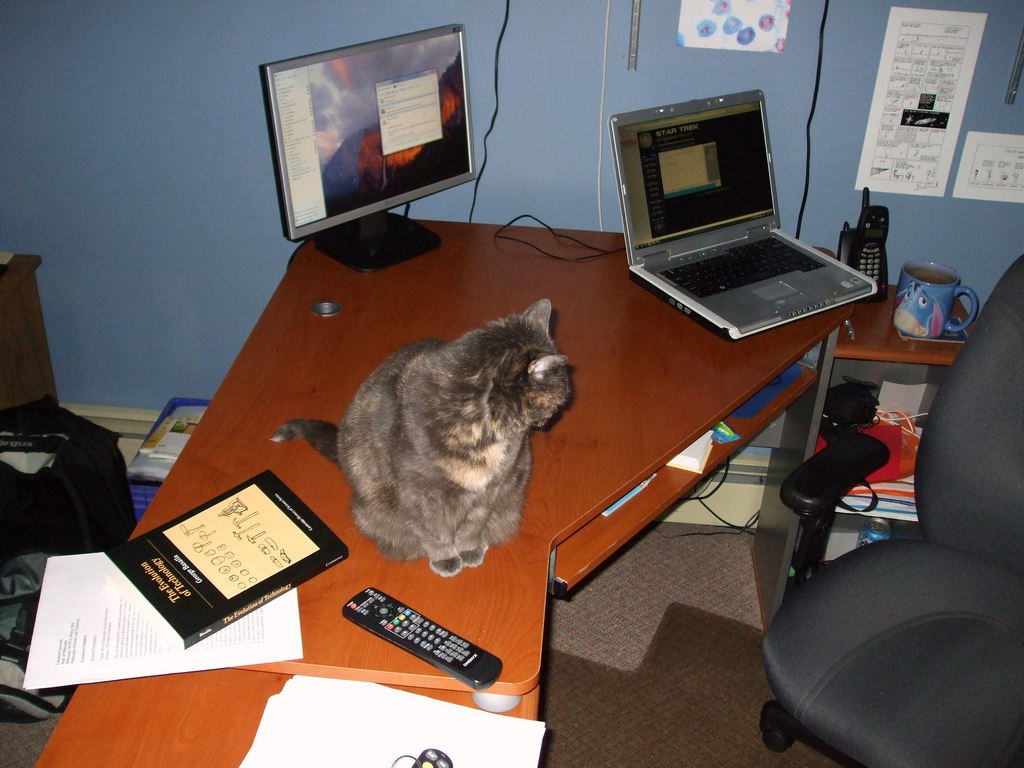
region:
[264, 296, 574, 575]
A cat sitting on a desk.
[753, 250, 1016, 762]
A grey desk chair with black arms.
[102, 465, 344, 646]
A black and beige book sitting on a paper.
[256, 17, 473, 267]
A silver framed monitor.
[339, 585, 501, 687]
A black remote is on the desk.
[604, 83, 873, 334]
An open laptop computer is on the desk.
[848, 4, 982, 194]
A long piece of paper is on the wall.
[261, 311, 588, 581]
A dark colored cat sitting on a desk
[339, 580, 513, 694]
A remote for a television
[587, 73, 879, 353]
A silver laptop turned on displaying STAR TREK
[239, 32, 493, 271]
A computer monitor with a cloudy background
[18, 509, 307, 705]
A letter or paper underneath a black textbook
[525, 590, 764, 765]
Plastic mat on the floor to let chair roll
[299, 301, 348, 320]
A hole in the desk to allow wires through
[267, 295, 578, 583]
Grey cat sitting on desk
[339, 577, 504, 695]
Black remote control on desk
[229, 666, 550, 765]
Stack of papers on desk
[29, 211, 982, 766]
Wooden desk against wall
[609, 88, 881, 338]
Silver laptop computer on desk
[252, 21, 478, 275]
Silver desktop computer monitor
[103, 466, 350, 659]
Black and cream colored book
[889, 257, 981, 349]
Light blue coffee mug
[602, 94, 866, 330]
a grey and black laptop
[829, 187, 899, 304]
a black portable phone in a charger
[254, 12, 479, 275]
a black and grey computer monitor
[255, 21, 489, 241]
an lcd computer screen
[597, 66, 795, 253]
a laptop's computer screen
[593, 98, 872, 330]
a thick laptop computer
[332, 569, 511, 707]
a black remote control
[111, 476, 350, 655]
a small black book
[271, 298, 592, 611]
a cat on a table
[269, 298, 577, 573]
a grey cat sits on a desk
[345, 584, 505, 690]
there is a remote control next to the cat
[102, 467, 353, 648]
there is a textbook by the cat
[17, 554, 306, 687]
a paper is underneath the textbook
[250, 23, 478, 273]
there is a monitor on the back corner of the desk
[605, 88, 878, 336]
there is a grey laptop in front of the monitor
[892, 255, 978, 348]
the mug is shaped like eeyore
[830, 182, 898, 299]
a cordless phone is on a side table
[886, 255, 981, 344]
the mug is next to the phone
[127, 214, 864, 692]
the computer desk is brown and wooden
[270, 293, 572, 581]
large furry grey cat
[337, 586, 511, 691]
large long black plastic controller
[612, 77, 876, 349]
large square plastic grey laptop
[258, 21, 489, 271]
large wide computer monitor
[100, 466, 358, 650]
large wide black book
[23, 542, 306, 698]
large wide white paper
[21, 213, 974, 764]
large wide wooden desk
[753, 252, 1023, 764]
large cloth grey chair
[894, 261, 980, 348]
small blue ceramic cup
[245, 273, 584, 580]
brown colored cat on the table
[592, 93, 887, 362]
laptop on the table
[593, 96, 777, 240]
screen of the laptop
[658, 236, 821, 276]
keyboard of the laptop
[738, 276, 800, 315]
trackpad of the laptop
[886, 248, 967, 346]
blue colored eeyore coffee mug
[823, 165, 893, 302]
black colored phone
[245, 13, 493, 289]
computer monitor on table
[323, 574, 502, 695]
black remote on table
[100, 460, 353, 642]
black colored book on table